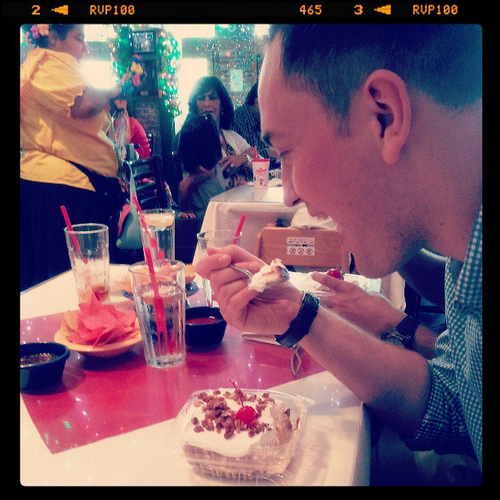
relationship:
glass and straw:
[127, 255, 189, 372] [141, 245, 178, 357]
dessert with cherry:
[177, 387, 296, 483] [237, 400, 259, 428]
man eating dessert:
[190, 21, 485, 471] [177, 387, 296, 483]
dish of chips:
[54, 323, 144, 362] [65, 290, 141, 349]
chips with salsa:
[65, 290, 141, 349] [186, 311, 224, 326]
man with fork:
[190, 21, 485, 471] [226, 260, 290, 291]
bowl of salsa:
[181, 306, 227, 350] [186, 311, 224, 326]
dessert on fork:
[177, 387, 296, 483] [226, 260, 290, 291]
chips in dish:
[65, 290, 141, 349] [54, 323, 144, 362]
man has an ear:
[190, 21, 485, 471] [361, 68, 413, 169]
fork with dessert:
[226, 260, 290, 291] [177, 387, 296, 483]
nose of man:
[280, 159, 299, 209] [190, 21, 485, 471]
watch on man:
[272, 293, 320, 348] [190, 21, 485, 471]